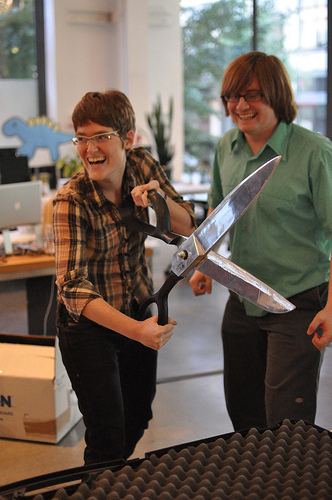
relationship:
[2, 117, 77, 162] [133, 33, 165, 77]
dinosaur on wall.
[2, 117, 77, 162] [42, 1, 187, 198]
dinosaur on wall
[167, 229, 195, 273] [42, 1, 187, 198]
dinosaur on wall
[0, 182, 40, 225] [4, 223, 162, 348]
laptop on desk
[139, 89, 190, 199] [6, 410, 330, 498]
plant on table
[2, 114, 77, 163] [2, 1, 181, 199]
dinosaur in wall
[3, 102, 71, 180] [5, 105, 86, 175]
artwork of dinosaur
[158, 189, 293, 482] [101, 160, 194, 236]
scissors with a handle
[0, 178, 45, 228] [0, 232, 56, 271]
laptop on a desk